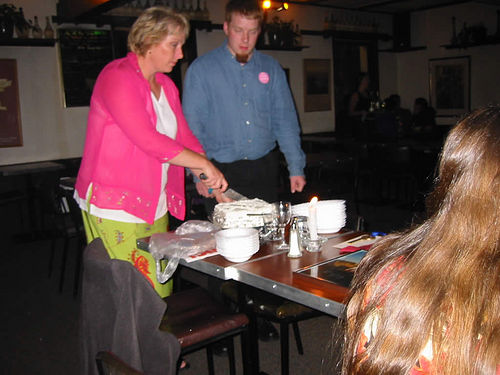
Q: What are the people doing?
A: Cutting.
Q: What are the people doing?
A: Celebrating.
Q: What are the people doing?
A: Cutting.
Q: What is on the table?
A: Cake.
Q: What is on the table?
A: Plate.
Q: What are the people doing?
A: Celebrating.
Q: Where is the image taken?
A: Living room.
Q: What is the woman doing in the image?
A: Cutting a slice of cake.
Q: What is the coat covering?
A: Back of chair.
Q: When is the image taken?
A: While cutting.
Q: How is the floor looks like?
A: Wooden.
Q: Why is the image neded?
A: Rememberance.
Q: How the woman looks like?
A: Fatty.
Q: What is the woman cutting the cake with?
A: A knife.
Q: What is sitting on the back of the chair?
A: A grey sweater.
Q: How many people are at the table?
A: Three.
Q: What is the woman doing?
A: Cutting a cake.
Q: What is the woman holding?
A: A knife.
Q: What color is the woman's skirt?
A: Green.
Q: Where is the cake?
A: On the table.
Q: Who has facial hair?
A: The man standing.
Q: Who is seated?
A: The girl near the camera.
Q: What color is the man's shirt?
A: Blue.